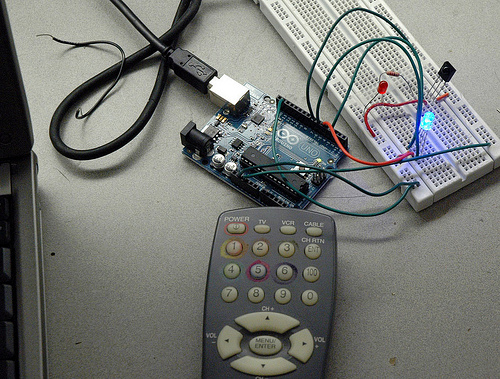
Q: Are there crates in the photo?
A: No, there are no crates.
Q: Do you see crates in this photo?
A: No, there are no crates.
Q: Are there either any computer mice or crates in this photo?
A: No, there are no crates or computer mice.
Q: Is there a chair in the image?
A: No, there are no chairs.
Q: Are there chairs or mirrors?
A: No, there are no chairs or mirrors.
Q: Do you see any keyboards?
A: Yes, there is a keyboard.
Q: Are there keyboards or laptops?
A: Yes, there is a keyboard.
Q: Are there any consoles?
A: No, there are no consoles.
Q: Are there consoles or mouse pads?
A: No, there are no consoles or mouse pads.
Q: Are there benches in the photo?
A: No, there are no benches.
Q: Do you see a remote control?
A: Yes, there is a remote control.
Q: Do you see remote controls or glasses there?
A: Yes, there is a remote control.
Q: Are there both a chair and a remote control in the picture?
A: No, there is a remote control but no chairs.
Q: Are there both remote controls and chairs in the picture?
A: No, there is a remote control but no chairs.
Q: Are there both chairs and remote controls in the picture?
A: No, there is a remote control but no chairs.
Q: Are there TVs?
A: No, there are no tvs.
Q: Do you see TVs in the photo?
A: No, there are no tvs.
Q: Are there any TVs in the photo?
A: No, there are no tvs.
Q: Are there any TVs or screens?
A: No, there are no TVs or screens.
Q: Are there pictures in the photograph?
A: No, there are no pictures.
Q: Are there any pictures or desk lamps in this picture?
A: No, there are no pictures or desk lamps.